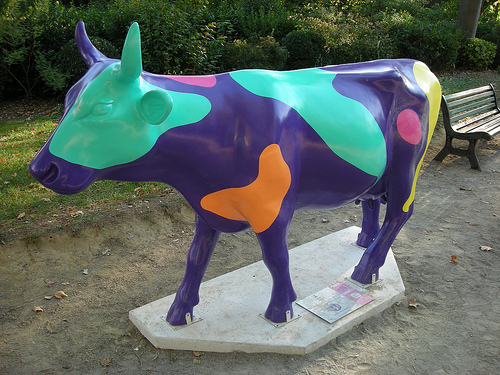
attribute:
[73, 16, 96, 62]
ear — his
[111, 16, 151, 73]
ear — his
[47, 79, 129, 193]
face — partial, green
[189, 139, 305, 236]
color — orange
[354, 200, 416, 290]
leg — his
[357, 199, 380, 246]
leg — his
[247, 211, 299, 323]
leg — his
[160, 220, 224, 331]
leg — his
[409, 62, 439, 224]
color — yellow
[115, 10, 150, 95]
horn — teal colored, ceramic, cow statue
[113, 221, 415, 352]
base — white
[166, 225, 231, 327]
leg — purple, cow statue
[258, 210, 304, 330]
leg — purple, cow statue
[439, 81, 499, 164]
bench — wood, metal, park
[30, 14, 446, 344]
statue — large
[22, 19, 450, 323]
statue — colorful, cow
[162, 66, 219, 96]
circle — large, pink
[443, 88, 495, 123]
slats — sunlit, wooden, bench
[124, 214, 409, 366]
statue base — white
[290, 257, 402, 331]
plaque — red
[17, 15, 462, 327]
statue cow — colorful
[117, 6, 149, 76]
horn — green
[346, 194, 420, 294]
leg — back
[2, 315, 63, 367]
imprints — small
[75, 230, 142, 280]
imprints — small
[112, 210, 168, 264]
imprints — small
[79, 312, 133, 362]
imprints — small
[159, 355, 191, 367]
imprints — small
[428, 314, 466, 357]
imprints — small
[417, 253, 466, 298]
imprints — small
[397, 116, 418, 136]
pink — paint